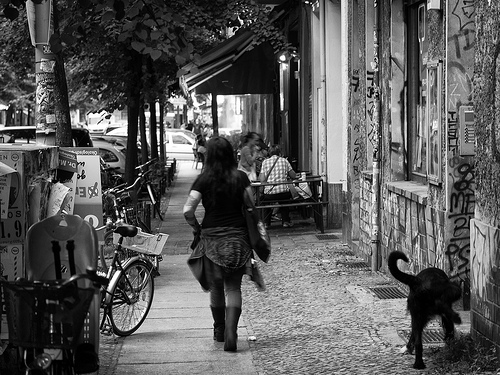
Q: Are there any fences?
A: No, there are no fences.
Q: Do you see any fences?
A: No, there are no fences.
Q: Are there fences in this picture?
A: No, there are no fences.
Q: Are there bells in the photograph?
A: No, there are no bells.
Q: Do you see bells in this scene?
A: No, there are no bells.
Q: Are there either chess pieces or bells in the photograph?
A: No, there are no bells or chess pieces.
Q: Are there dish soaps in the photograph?
A: No, there are no dish soaps.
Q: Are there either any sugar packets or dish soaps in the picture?
A: No, there are no dish soaps or sugar packets.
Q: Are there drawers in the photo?
A: No, there are no drawers.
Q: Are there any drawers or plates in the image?
A: No, there are no drawers or plates.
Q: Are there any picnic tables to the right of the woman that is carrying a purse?
A: Yes, there is a picnic table to the right of the woman.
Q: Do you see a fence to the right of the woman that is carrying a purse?
A: No, there is a picnic table to the right of the woman.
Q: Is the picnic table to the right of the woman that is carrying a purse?
A: Yes, the picnic table is to the right of the woman.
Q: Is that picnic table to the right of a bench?
A: No, the picnic table is to the right of the woman.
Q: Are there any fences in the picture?
A: No, there are no fences.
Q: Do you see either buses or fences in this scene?
A: No, there are no fences or buses.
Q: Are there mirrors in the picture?
A: No, there are no mirrors.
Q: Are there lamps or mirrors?
A: No, there are no mirrors or lamps.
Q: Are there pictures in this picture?
A: No, there are no pictures.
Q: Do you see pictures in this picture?
A: No, there are no pictures.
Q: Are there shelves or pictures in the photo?
A: No, there are no pictures or shelves.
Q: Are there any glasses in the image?
A: No, there are no glasses.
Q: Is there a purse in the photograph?
A: Yes, there is a purse.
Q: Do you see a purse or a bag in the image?
A: Yes, there is a purse.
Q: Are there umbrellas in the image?
A: No, there are no umbrellas.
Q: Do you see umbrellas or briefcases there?
A: No, there are no umbrellas or briefcases.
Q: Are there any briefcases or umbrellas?
A: No, there are no umbrellas or briefcases.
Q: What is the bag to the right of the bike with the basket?
A: The bag is a purse.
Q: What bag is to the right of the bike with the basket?
A: The bag is a purse.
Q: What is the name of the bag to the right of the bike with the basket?
A: The bag is a purse.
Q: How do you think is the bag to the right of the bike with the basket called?
A: The bag is a purse.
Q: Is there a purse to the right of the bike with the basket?
A: Yes, there is a purse to the right of the bike.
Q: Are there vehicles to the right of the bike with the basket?
A: No, there is a purse to the right of the bike.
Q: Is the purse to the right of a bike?
A: Yes, the purse is to the right of a bike.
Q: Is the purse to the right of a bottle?
A: No, the purse is to the right of a bike.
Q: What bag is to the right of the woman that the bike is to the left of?
A: The bag is a purse.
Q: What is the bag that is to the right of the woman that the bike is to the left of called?
A: The bag is a purse.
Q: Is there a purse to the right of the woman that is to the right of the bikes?
A: Yes, there is a purse to the right of the woman.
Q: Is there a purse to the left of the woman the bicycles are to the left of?
A: No, the purse is to the right of the woman.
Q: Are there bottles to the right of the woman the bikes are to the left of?
A: No, there is a purse to the right of the woman.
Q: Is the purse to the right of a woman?
A: Yes, the purse is to the right of a woman.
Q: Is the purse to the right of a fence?
A: No, the purse is to the right of a woman.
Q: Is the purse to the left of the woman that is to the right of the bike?
A: No, the purse is to the right of the woman.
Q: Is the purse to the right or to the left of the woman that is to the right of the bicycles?
A: The purse is to the right of the woman.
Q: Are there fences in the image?
A: No, there are no fences.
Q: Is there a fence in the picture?
A: No, there are no fences.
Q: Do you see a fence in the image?
A: No, there are no fences.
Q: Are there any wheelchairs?
A: No, there are no wheelchairs.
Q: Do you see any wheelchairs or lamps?
A: No, there are no wheelchairs or lamps.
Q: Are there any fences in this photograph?
A: No, there are no fences.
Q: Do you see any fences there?
A: No, there are no fences.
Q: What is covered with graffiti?
A: The building is covered with graffiti.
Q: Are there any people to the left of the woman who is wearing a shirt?
A: Yes, there is a person to the left of the woman.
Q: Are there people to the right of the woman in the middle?
A: No, the person is to the left of the woman.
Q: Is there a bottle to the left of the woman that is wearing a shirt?
A: No, there is a person to the left of the woman.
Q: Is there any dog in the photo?
A: Yes, there is a dog.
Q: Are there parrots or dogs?
A: Yes, there is a dog.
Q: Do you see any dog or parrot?
A: Yes, there is a dog.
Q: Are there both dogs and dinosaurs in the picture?
A: No, there is a dog but no dinosaurs.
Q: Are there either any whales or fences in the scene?
A: No, there are no fences or whales.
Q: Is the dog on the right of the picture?
A: Yes, the dog is on the right of the image.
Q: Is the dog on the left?
A: No, the dog is on the right of the image.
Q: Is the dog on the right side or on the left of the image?
A: The dog is on the right of the image.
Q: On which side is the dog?
A: The dog is on the right of the image.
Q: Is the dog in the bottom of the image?
A: Yes, the dog is in the bottom of the image.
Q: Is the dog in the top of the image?
A: No, the dog is in the bottom of the image.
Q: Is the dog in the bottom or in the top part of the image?
A: The dog is in the bottom of the image.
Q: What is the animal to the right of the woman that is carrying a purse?
A: The animal is a dog.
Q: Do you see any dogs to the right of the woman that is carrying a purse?
A: Yes, there is a dog to the right of the woman.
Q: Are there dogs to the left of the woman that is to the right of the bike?
A: No, the dog is to the right of the woman.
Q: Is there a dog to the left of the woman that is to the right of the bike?
A: No, the dog is to the right of the woman.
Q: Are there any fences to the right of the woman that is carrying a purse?
A: No, there is a dog to the right of the woman.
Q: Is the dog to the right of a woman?
A: Yes, the dog is to the right of a woman.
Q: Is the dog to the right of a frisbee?
A: No, the dog is to the right of a woman.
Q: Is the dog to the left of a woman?
A: No, the dog is to the right of a woman.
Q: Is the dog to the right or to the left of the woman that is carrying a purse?
A: The dog is to the right of the woman.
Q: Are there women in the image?
A: Yes, there is a woman.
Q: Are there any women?
A: Yes, there is a woman.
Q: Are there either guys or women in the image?
A: Yes, there is a woman.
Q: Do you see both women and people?
A: Yes, there are both a woman and a person.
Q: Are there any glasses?
A: No, there are no glasses.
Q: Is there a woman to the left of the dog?
A: Yes, there is a woman to the left of the dog.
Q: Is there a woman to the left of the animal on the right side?
A: Yes, there is a woman to the left of the dog.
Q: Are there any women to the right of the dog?
A: No, the woman is to the left of the dog.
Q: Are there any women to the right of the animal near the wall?
A: No, the woman is to the left of the dog.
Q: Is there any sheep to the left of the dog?
A: No, there is a woman to the left of the dog.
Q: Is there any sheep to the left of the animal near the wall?
A: No, there is a woman to the left of the dog.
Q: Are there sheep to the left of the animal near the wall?
A: No, there is a woman to the left of the dog.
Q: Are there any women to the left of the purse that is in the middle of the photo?
A: Yes, there is a woman to the left of the purse.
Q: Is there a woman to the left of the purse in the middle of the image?
A: Yes, there is a woman to the left of the purse.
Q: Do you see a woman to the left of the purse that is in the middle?
A: Yes, there is a woman to the left of the purse.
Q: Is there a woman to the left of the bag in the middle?
A: Yes, there is a woman to the left of the purse.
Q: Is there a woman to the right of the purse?
A: No, the woman is to the left of the purse.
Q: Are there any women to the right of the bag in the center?
A: No, the woman is to the left of the purse.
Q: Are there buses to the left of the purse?
A: No, there is a woman to the left of the purse.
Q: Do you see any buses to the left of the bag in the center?
A: No, there is a woman to the left of the purse.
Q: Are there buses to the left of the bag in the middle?
A: No, there is a woman to the left of the purse.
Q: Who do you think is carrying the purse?
A: The woman is carrying the purse.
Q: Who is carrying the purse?
A: The woman is carrying the purse.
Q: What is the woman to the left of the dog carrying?
A: The woman is carrying a purse.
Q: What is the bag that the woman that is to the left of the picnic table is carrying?
A: The bag is a purse.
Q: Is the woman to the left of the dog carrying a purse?
A: Yes, the woman is carrying a purse.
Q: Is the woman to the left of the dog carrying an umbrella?
A: No, the woman is carrying a purse.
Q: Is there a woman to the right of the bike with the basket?
A: Yes, there is a woman to the right of the bike.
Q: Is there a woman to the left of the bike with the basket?
A: No, the woman is to the right of the bike.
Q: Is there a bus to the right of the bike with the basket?
A: No, there is a woman to the right of the bike.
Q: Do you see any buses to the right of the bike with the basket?
A: No, there is a woman to the right of the bike.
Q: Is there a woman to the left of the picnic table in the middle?
A: Yes, there is a woman to the left of the picnic table.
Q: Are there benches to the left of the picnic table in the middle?
A: No, there is a woman to the left of the picnic table.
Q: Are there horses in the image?
A: No, there are no horses.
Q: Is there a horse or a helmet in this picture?
A: No, there are no horses or helmets.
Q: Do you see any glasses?
A: No, there are no glasses.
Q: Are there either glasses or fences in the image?
A: No, there are no glasses or fences.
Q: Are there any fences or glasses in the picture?
A: No, there are no glasses or fences.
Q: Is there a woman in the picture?
A: Yes, there is a woman.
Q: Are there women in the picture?
A: Yes, there is a woman.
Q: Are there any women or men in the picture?
A: Yes, there is a woman.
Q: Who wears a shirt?
A: The woman wears a shirt.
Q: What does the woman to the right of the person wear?
A: The woman wears a shirt.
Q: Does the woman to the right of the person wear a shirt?
A: Yes, the woman wears a shirt.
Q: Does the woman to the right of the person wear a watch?
A: No, the woman wears a shirt.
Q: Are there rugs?
A: No, there are no rugs.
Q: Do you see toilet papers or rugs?
A: No, there are no rugs or toilet papers.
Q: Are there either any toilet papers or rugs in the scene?
A: No, there are no rugs or toilet papers.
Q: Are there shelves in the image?
A: No, there are no shelves.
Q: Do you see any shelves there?
A: No, there are no shelves.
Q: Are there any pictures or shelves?
A: No, there are no shelves or pictures.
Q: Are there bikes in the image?
A: Yes, there is a bike.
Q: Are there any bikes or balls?
A: Yes, there is a bike.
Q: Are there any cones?
A: No, there are no cones.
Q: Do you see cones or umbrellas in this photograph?
A: No, there are no cones or umbrellas.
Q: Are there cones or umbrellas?
A: No, there are no cones or umbrellas.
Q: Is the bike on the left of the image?
A: Yes, the bike is on the left of the image.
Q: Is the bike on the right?
A: No, the bike is on the left of the image.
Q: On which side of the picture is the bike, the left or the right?
A: The bike is on the left of the image.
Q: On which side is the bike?
A: The bike is on the left of the image.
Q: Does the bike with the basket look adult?
A: Yes, the bike is adult.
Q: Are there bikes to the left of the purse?
A: Yes, there is a bike to the left of the purse.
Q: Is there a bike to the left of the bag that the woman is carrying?
A: Yes, there is a bike to the left of the purse.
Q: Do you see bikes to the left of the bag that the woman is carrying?
A: Yes, there is a bike to the left of the purse.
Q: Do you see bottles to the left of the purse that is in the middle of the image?
A: No, there is a bike to the left of the purse.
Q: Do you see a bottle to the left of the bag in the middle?
A: No, there is a bike to the left of the purse.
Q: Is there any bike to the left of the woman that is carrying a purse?
A: Yes, there is a bike to the left of the woman.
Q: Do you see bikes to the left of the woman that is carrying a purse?
A: Yes, there is a bike to the left of the woman.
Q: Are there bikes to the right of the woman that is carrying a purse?
A: No, the bike is to the left of the woman.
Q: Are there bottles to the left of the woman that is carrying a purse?
A: No, there is a bike to the left of the woman.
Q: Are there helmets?
A: No, there are no helmets.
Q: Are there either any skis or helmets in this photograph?
A: No, there are no helmets or skis.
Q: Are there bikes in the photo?
A: Yes, there are bikes.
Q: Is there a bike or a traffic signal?
A: Yes, there are bikes.